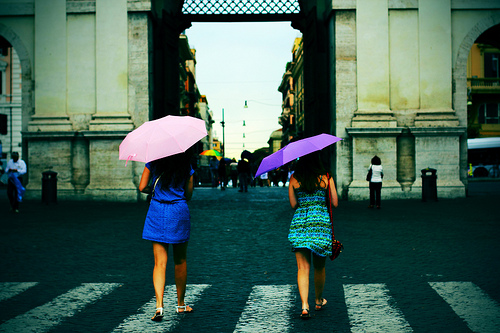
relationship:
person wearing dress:
[137, 153, 195, 320] [141, 151, 194, 242]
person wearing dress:
[286, 153, 344, 317] [287, 185, 333, 258]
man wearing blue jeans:
[4, 152, 27, 213] [9, 170, 25, 203]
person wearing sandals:
[137, 153, 195, 320] [151, 302, 196, 319]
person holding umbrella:
[137, 153, 195, 320] [117, 113, 207, 165]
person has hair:
[137, 153, 195, 320] [143, 148, 198, 194]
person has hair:
[137, 153, 195, 320] [148, 148, 191, 192]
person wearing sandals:
[137, 146, 199, 323] [149, 302, 196, 322]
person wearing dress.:
[286, 153, 344, 317] [286, 183, 346, 255]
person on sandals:
[233, 134, 385, 316] [284, 294, 354, 314]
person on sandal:
[286, 153, 344, 317] [298, 307, 311, 319]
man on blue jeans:
[1, 152, 28, 205] [5, 170, 25, 204]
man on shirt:
[1, 152, 28, 205] [5, 160, 26, 171]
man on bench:
[1, 152, 28, 205] [5, 172, 27, 184]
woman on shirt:
[363, 151, 393, 208] [365, 163, 382, 182]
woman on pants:
[363, 151, 393, 208] [366, 185, 381, 202]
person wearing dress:
[137, 153, 195, 320] [280, 166, 339, 266]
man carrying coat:
[4, 152, 27, 213] [4, 159, 26, 177]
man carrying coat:
[4, 152, 27, 213] [4, 166, 32, 208]